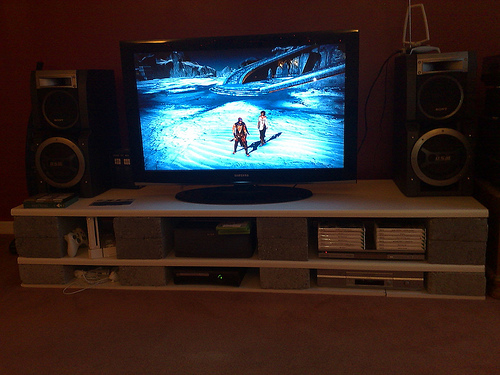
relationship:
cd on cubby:
[377, 227, 427, 251] [296, 216, 439, 263]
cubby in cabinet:
[296, 216, 439, 263] [10, 178, 487, 302]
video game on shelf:
[307, 218, 429, 297] [308, 214, 425, 291]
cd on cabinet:
[377, 227, 427, 251] [10, 178, 487, 302]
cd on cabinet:
[317, 227, 366, 251] [10, 178, 487, 302]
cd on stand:
[310, 217, 366, 264] [13, 166, 498, 313]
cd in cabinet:
[372, 220, 426, 254] [10, 178, 487, 302]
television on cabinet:
[118, 27, 356, 209] [10, 178, 487, 302]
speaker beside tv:
[388, 41, 487, 197] [118, 27, 359, 204]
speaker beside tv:
[25, 63, 127, 199] [118, 27, 359, 204]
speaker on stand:
[25, 63, 127, 199] [13, 166, 498, 313]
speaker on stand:
[388, 41, 479, 195] [13, 166, 498, 313]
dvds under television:
[298, 225, 444, 287] [118, 28, 361, 205]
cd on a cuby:
[317, 227, 366, 251] [306, 220, 430, 262]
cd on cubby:
[377, 227, 427, 251] [304, 216, 432, 263]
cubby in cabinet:
[304, 216, 432, 263] [10, 178, 487, 302]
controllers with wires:
[67, 262, 123, 283] [63, 261, 117, 286]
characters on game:
[230, 107, 272, 157] [168, 267, 243, 287]